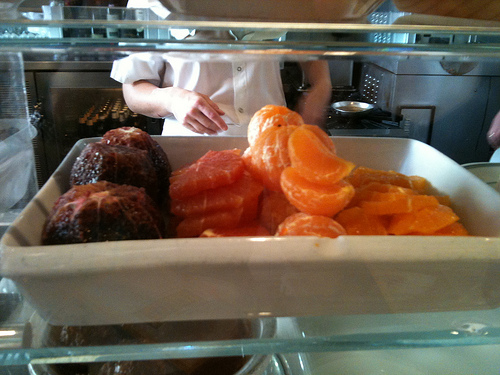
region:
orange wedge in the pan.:
[298, 138, 330, 172]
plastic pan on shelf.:
[130, 257, 260, 280]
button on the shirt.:
[235, 64, 243, 74]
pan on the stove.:
[338, 97, 370, 113]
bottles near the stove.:
[87, 106, 127, 120]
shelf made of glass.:
[217, 326, 339, 348]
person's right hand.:
[180, 94, 212, 129]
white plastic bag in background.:
[2, 153, 23, 204]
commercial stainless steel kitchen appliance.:
[445, 89, 465, 129]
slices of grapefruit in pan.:
[198, 160, 235, 197]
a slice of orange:
[287, 127, 347, 184]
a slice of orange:
[280, 168, 357, 216]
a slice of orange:
[269, 213, 340, 241]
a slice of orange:
[354, 195, 404, 213]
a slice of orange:
[346, 216, 381, 236]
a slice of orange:
[400, 208, 454, 233]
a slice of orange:
[349, 163, 409, 186]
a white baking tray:
[3, 127, 495, 329]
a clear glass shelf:
[0, 282, 497, 369]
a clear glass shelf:
[0, 13, 497, 72]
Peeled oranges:
[245, 108, 344, 244]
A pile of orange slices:
[355, 170, 450, 242]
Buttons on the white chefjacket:
[232, 60, 248, 122]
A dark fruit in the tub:
[37, 123, 169, 246]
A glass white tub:
[4, 241, 498, 319]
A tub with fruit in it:
[49, 129, 498, 311]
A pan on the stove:
[322, 91, 407, 128]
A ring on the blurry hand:
[489, 130, 494, 142]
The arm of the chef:
[123, 71, 227, 138]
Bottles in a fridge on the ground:
[70, 91, 134, 131]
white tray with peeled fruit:
[25, 130, 475, 327]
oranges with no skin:
[273, 139, 354, 219]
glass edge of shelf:
[223, 316, 454, 363]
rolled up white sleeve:
[105, 57, 170, 106]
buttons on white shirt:
[226, 64, 255, 120]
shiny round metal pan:
[330, 93, 379, 125]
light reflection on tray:
[407, 133, 461, 185]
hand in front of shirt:
[171, 87, 232, 139]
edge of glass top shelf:
[213, 12, 419, 42]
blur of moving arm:
[298, 60, 340, 116]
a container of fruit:
[10, 46, 496, 356]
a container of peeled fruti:
[57, 85, 428, 346]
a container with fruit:
[32, 100, 444, 371]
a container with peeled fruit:
[24, 92, 483, 354]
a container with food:
[28, 95, 492, 367]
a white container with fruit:
[43, 90, 476, 365]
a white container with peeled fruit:
[23, 60, 498, 352]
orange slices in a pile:
[250, 63, 426, 259]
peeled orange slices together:
[211, 50, 473, 327]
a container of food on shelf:
[47, 115, 429, 357]